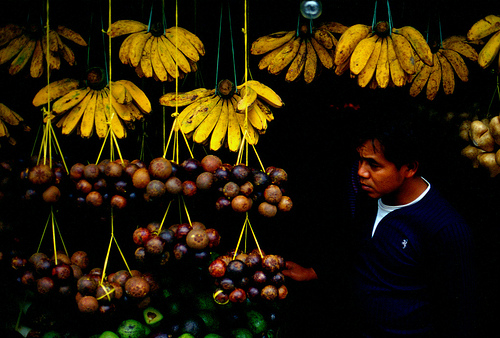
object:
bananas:
[106, 20, 207, 82]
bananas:
[251, 22, 351, 84]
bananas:
[32, 67, 151, 138]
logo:
[402, 239, 409, 249]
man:
[345, 129, 467, 338]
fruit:
[215, 164, 292, 218]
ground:
[296, 319, 499, 338]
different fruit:
[0, 20, 292, 338]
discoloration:
[187, 107, 209, 123]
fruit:
[0, 155, 293, 217]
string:
[232, 8, 266, 172]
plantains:
[3, 18, 498, 153]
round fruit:
[10, 158, 68, 206]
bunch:
[1, 102, 30, 145]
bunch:
[0, 25, 87, 78]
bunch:
[32, 68, 153, 139]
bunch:
[106, 19, 204, 83]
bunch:
[159, 79, 285, 152]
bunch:
[249, 22, 349, 83]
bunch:
[334, 21, 434, 88]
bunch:
[407, 35, 480, 101]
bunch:
[467, 14, 500, 69]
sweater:
[337, 173, 480, 337]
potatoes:
[458, 112, 498, 177]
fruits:
[75, 268, 159, 316]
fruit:
[207, 248, 289, 306]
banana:
[159, 80, 284, 153]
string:
[367, 3, 397, 38]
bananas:
[332, 21, 434, 88]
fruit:
[130, 221, 221, 267]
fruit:
[131, 155, 220, 202]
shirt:
[339, 173, 474, 338]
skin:
[207, 107, 229, 126]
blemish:
[187, 115, 194, 124]